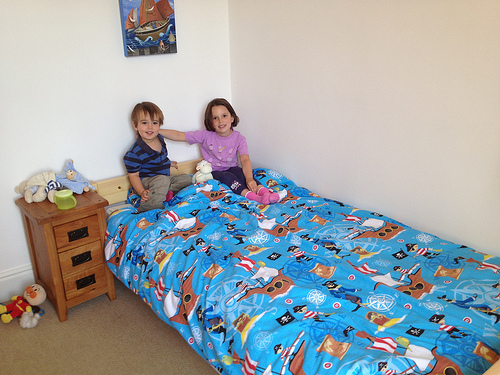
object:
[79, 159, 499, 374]
bed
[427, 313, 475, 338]
pirate design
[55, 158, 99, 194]
animals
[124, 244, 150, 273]
pirate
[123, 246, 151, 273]
design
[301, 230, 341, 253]
pirates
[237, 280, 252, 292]
pirates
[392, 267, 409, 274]
pirates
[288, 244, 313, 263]
pirate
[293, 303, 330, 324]
pirate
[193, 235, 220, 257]
pirate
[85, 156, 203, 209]
bed head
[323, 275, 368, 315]
pirate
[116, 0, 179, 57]
photo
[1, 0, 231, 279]
wall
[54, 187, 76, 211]
tea cup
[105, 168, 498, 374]
bed cover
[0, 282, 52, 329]
stuffed duck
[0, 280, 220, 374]
ground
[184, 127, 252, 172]
purple shirt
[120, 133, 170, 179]
shirt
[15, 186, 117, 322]
dresser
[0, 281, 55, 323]
animal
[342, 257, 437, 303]
design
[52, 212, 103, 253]
drawer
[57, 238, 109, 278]
drawer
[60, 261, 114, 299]
drawer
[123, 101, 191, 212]
boy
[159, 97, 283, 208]
girl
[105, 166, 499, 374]
cloth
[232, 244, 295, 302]
boat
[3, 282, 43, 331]
duck